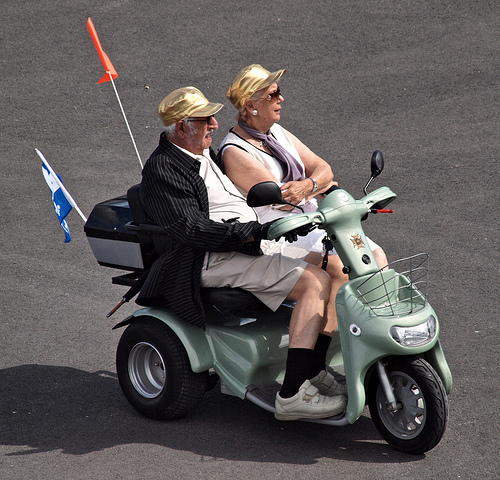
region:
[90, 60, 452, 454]
Elderly couple on a three wheeler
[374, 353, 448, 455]
Front tire of scooter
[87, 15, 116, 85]
Orange flag on back of scooter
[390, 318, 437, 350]
Headlight on front of scooter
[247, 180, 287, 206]
Side view mirror on scooter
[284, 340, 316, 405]
Black sock on man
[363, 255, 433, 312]
Wire basket on scooter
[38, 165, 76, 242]
Blue and white flag on scooter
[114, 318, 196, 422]
Rear tire on scooter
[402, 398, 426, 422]
part of a wheel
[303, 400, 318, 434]
part of a short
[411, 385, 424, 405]
edge of a wheel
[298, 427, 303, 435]
part of a shadow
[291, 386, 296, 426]
part of a sock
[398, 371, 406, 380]
part of a wheel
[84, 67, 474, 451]
two people riding on a scooter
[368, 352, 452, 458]
the front wheel of the scooter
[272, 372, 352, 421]
a pair of white shoes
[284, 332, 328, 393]
ankle high black socks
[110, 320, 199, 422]
the thick back wheel of the scooter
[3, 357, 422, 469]
a shadow cast on the ground by the scooter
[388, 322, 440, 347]
a light on the front of the scooter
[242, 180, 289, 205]
a side mirror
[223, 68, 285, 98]
a golden hat on the woman's head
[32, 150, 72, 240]
a blue and white flag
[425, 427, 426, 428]
part of a wheel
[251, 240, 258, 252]
part of a short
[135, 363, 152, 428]
part of a shadow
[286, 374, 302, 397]
part of a sock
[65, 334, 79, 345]
Heart shaped donut with sprinkles.